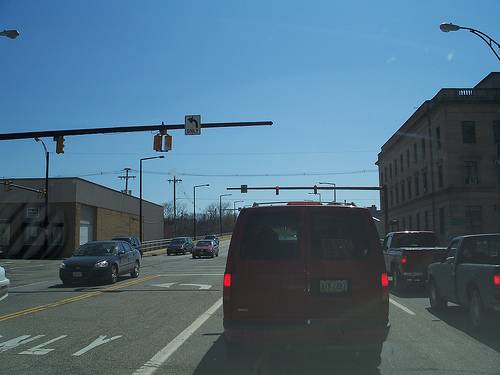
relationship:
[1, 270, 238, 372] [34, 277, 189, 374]
lines on street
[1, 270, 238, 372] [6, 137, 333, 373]
lines painted on street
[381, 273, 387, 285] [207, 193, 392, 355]
light on vehicles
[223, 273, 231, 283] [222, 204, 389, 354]
light on vehicle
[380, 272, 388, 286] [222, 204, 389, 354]
light on vehicle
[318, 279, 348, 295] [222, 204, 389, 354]
license tag on vehicle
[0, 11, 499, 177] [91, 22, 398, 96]
cloud in sky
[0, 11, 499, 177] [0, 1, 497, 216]
cloud in sky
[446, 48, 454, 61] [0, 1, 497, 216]
cloud in sky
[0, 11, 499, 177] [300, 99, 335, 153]
cloud in sky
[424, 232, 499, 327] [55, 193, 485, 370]
truck stopping in traffic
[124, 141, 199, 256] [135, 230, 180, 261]
lamp standing on sidewalk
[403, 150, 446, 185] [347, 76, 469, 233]
windows along side of building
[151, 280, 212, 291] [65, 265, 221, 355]
arrow painted on street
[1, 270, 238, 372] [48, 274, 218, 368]
lines in street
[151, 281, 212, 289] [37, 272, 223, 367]
arrow on street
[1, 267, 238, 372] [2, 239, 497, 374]
lines in road